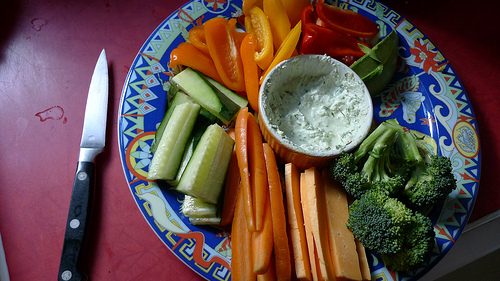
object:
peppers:
[201, 16, 240, 94]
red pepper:
[301, 3, 378, 58]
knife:
[56, 46, 112, 278]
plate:
[118, 3, 476, 271]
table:
[1, 1, 498, 279]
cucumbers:
[146, 65, 251, 227]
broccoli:
[333, 122, 425, 200]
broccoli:
[403, 125, 459, 207]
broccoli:
[344, 188, 416, 257]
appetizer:
[147, 0, 477, 276]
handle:
[56, 161, 98, 271]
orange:
[168, 17, 263, 114]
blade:
[76, 45, 112, 151]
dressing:
[300, 92, 336, 120]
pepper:
[238, 31, 262, 114]